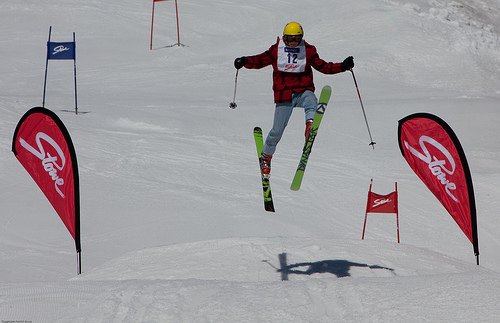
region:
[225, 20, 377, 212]
skier skiing down the hill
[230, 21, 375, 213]
skier jumping in the air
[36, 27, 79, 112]
blue flag in the snow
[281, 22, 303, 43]
yellow helmet on the skier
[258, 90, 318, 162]
white pants on the skier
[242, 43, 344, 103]
black and red coat on the skier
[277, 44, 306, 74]
white bib with the number 12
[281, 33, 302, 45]
tinted goggles on the skier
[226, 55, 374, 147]
ski poles in the skiers hands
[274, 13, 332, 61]
the head of a man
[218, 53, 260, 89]
the hand of a man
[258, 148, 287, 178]
the foot of a man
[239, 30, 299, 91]
the arm of a man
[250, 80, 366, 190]
the legs of a man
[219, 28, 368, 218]
a man on skis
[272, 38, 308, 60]
the chin of a man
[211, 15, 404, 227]
a man in the air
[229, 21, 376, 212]
The skier is jumping.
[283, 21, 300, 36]
The skier wears a helmet.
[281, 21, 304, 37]
The helmet is yellow.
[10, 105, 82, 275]
A flag is in the snow.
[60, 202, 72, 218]
The flag is red.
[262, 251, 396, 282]
The skier's shadow is on the ground.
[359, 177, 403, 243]
A course marker is in the snow.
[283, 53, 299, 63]
The number 12 is on the skier.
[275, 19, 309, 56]
head of a person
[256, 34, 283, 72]
arm of a person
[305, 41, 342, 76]
arm of a person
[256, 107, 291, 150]
leg of a person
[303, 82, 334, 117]
leg of a person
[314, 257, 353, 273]
shadow of a person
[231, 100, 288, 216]
person wearing a ski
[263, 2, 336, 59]
person wearing a helmet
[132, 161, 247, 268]
a ground covered in snow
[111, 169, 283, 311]
a ground covered in white snow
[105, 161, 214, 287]
snow covering the ground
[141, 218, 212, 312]
white snow covering the ground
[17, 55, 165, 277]
a banner in the snow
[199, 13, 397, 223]
a person that is skiing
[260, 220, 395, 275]
a skiers shadow on the ground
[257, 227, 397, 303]
a skiers shadow on the snow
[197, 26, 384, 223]
a person holding ski poles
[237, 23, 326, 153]
a person wearing a helmet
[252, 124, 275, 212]
the black white and green long ski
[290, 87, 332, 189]
the black white and green long ski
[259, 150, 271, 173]
the red plastic ski boot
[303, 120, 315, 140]
the red plastic ski boot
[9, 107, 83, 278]
the red white and black flag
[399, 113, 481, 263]
the red white and black flag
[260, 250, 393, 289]
the dark shadow of the skier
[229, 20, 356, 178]
the flying skier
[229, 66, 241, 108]
the long black ski pole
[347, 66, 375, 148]
the long black ski pole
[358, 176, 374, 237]
pole sticking out of the ski run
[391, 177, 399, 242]
pole sticking out of the ski run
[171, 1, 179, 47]
pole sticking out of the ski run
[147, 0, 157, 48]
pole sticking out of the ski run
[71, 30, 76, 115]
pole sticking out of the ski run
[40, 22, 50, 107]
pole sticking out of the ski run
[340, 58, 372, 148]
pole sticking out of the ski run